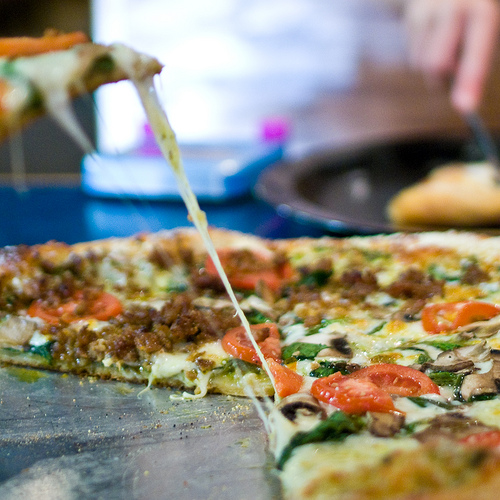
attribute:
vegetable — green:
[275, 408, 357, 473]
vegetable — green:
[427, 368, 464, 388]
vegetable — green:
[24, 339, 56, 360]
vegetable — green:
[417, 338, 459, 350]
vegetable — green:
[278, 340, 326, 363]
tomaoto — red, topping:
[369, 358, 441, 403]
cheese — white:
[132, 81, 287, 407]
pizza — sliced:
[4, 31, 199, 129]